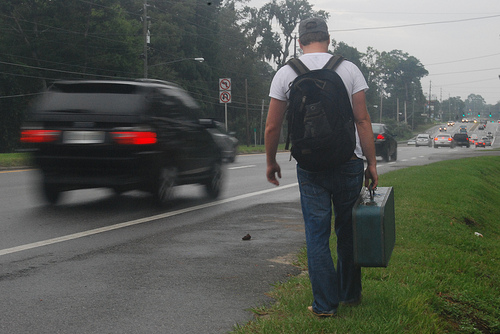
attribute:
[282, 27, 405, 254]
man — walking, foreground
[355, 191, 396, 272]
suitcase — green, old fashioned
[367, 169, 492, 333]
area — grassy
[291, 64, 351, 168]
backpack — black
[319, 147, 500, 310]
grass — green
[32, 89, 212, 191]
car — black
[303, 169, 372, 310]
jeans — blue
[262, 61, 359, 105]
shirt — white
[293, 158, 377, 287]
pants — blue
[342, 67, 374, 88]
sleeves — short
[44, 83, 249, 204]
suv — black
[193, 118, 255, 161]
vehicle — silver, stopped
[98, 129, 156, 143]
lights — on